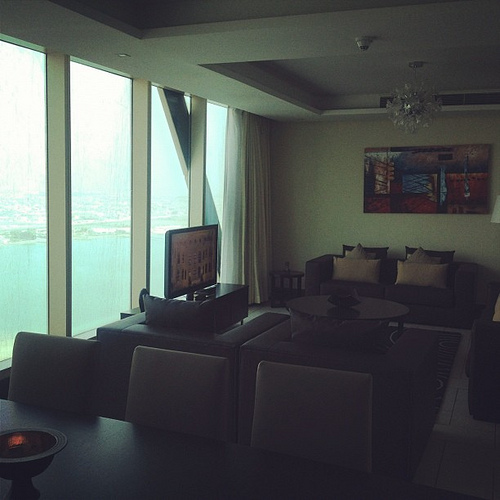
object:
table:
[286, 294, 409, 320]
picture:
[363, 144, 490, 216]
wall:
[270, 119, 499, 290]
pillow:
[331, 255, 380, 284]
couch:
[304, 253, 478, 329]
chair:
[251, 360, 373, 471]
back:
[251, 359, 372, 471]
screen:
[164, 224, 218, 299]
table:
[171, 283, 249, 334]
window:
[70, 61, 132, 336]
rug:
[388, 326, 463, 429]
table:
[0, 398, 482, 500]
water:
[3, 236, 165, 357]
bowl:
[327, 292, 359, 306]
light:
[385, 82, 443, 135]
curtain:
[219, 106, 273, 305]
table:
[270, 270, 304, 307]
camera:
[355, 36, 373, 51]